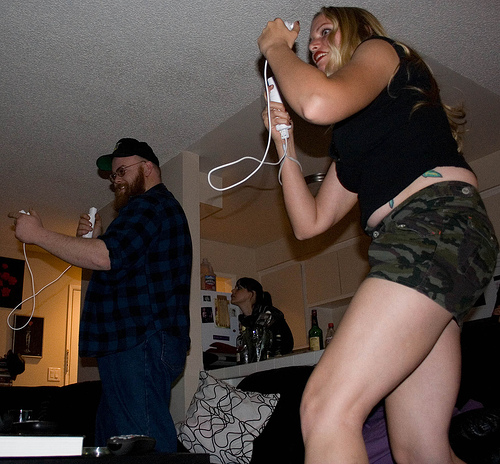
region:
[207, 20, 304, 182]
wii controllers in the woman's hands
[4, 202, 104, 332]
wii controllers in the man's hands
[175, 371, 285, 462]
black and white pillow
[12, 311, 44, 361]
framed picture on the wall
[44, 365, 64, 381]
light switch on the wall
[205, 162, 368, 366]
kitchen area behind living room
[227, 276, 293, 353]
woman standing in the kitchen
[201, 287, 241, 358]
white refrigerator with magnets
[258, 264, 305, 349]
beige color cabinets in the kitchen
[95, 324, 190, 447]
blue jeans on the man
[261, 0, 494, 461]
woman dressed in black shirt and camo patterned shorts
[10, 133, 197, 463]
man dressed in blue an black plaid shirt and jeans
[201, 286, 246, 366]
a refrigerator in a kitchen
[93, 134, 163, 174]
a baseball cap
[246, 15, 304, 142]
a woman's hand holding video game remote controls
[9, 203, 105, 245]
a man's hands holding video game remote controls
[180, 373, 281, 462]
a throw pillow with a brown pattern on it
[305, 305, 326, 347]
a bottle sitting on a kitchen countertop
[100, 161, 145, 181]
eyeglasses on a man's face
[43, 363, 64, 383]
a white lightswitch on the wall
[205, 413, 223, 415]
part of a pillow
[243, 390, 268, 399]
edge of a pillow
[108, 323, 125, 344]
part of a shirt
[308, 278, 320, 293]
part of a drawer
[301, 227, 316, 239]
part of an elbow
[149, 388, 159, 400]
part of a jeans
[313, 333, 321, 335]
part of a bottle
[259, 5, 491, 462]
woman playing the wii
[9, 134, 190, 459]
man playing the wii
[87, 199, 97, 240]
wii controller in the man's han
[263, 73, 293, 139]
wii controller in the woman's hand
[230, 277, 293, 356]
person standing in the kitchen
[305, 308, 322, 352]
bottle sitting on the kitchen counter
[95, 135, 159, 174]
black hat on the man's head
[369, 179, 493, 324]
camoflauge shorts on the woman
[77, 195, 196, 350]
black and blue checker shirt on the man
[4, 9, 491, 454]
two people playing the wii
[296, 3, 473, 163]
young girl with long blonde hair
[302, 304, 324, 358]
a green glass bottle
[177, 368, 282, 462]
a white with black stripe throw pillow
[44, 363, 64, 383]
two white light switch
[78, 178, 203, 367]
blue and black checkered shirt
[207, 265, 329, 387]
a young girl standing on otherside of counter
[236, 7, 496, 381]
young girl wearing black tank top and shorts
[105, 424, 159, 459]
a grey remote control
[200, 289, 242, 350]
picture hanging up on fridge